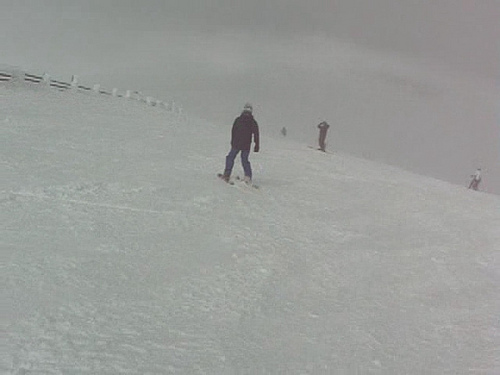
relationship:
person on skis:
[201, 95, 260, 172] [212, 181, 269, 185]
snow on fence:
[30, 168, 129, 199] [20, 72, 78, 90]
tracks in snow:
[87, 193, 168, 221] [30, 168, 129, 199]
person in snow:
[201, 95, 260, 172] [30, 168, 129, 199]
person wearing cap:
[201, 95, 260, 172] [243, 98, 255, 110]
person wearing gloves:
[201, 95, 260, 172] [251, 142, 259, 150]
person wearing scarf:
[201, 95, 260, 172] [242, 122, 258, 127]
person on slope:
[201, 95, 260, 172] [21, 98, 77, 141]